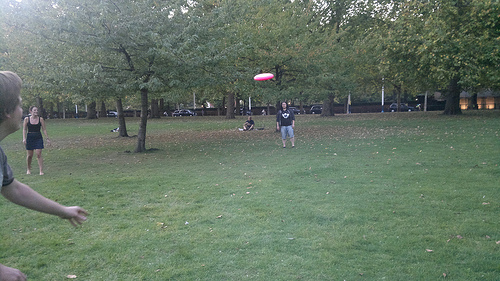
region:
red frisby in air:
[245, 60, 277, 87]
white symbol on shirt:
[280, 110, 290, 120]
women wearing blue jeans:
[280, 127, 286, 137]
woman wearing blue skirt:
[31, 136, 38, 146]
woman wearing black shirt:
[29, 123, 39, 130]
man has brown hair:
[3, 77, 13, 93]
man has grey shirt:
[2, 162, 12, 178]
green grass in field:
[244, 205, 284, 232]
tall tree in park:
[442, 29, 458, 82]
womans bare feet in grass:
[19, 167, 51, 178]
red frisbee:
[235, 56, 286, 88]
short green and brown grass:
[337, 216, 375, 243]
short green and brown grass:
[384, 203, 414, 225]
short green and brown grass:
[221, 161, 261, 206]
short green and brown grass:
[164, 185, 185, 203]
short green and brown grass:
[327, 181, 362, 202]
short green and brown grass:
[218, 169, 288, 224]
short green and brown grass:
[147, 201, 208, 235]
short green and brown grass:
[375, 132, 425, 162]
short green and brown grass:
[215, 191, 272, 218]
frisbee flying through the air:
[238, 66, 276, 89]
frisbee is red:
[250, 65, 271, 80]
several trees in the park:
[0, 2, 482, 152]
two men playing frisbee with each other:
[0, 65, 310, 275]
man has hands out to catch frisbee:
[0, 70, 87, 275]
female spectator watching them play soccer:
[15, 100, 51, 170]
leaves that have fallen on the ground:
[75, 120, 405, 140]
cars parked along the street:
[85, 100, 410, 111]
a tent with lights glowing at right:
[450, 90, 495, 112]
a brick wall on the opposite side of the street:
[167, 91, 417, 113]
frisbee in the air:
[250, 62, 280, 88]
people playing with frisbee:
[1, 53, 312, 271]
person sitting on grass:
[222, 105, 269, 143]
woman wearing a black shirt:
[24, 113, 44, 137]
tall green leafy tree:
[405, 6, 482, 120]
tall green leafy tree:
[198, 10, 247, 117]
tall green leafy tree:
[91, 7, 193, 163]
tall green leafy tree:
[81, 20, 138, 147]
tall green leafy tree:
[48, 3, 101, 125]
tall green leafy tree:
[6, 7, 56, 92]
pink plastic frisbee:
[252, 72, 275, 81]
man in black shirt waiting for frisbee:
[275, 98, 299, 150]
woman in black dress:
[21, 99, 50, 179]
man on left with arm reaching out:
[0, 61, 91, 277]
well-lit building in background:
[450, 88, 496, 108]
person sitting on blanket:
[239, 111, 254, 133]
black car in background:
[173, 104, 193, 119]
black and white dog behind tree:
[110, 123, 122, 133]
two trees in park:
[37, 0, 257, 163]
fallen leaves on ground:
[62, 118, 424, 148]